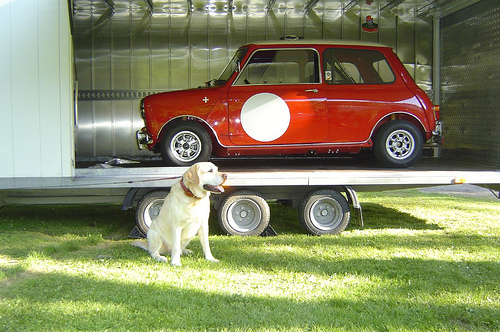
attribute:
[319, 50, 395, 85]
window — rear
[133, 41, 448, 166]
red car — small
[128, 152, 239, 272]
lab — yellow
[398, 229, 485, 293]
grass — green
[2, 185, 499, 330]
grass — green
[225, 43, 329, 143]
door — circular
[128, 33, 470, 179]
car — white, circle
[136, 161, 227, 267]
lab — big, yellow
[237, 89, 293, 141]
circle — white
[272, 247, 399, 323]
grass — green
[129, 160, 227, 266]
dog — sitting 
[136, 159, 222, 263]
lab — yellow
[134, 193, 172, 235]
tire — gray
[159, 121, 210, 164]
tire — black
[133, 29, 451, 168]
car — small, red, white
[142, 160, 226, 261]
dog — white 